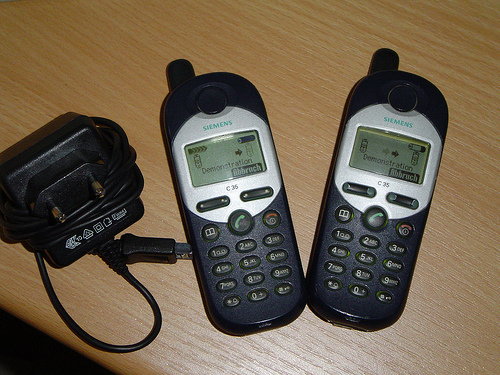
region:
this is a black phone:
[165, 37, 291, 320]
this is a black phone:
[311, 80, 454, 322]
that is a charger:
[7, 135, 165, 251]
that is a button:
[206, 245, 227, 256]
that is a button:
[236, 233, 251, 250]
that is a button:
[267, 251, 287, 261]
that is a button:
[247, 286, 262, 302]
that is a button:
[323, 256, 336, 271]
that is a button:
[350, 228, 381, 249]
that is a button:
[322, 277, 347, 292]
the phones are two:
[169, 68, 430, 326]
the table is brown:
[272, 338, 402, 373]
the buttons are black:
[221, 230, 286, 296]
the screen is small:
[177, 128, 274, 187]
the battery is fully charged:
[236, 128, 258, 148]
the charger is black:
[18, 126, 172, 331]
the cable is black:
[57, 308, 172, 371]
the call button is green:
[230, 213, 255, 230]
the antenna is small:
[165, 58, 200, 83]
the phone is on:
[338, 45, 440, 331]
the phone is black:
[338, 75, 438, 326]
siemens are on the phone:
[381, 110, 427, 133]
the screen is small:
[355, 129, 432, 185]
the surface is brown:
[270, 31, 332, 116]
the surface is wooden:
[280, 13, 330, 109]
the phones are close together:
[161, 69, 438, 323]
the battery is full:
[237, 134, 258, 147]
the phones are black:
[157, 54, 432, 331]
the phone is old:
[154, 60, 305, 326]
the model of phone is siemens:
[162, 74, 311, 340]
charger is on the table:
[19, 110, 200, 341]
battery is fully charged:
[234, 131, 261, 145]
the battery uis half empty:
[405, 145, 428, 154]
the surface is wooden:
[272, 54, 318, 141]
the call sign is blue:
[365, 210, 385, 225]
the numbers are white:
[226, 237, 293, 301]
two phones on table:
[150, 65, 412, 340]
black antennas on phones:
[362, 41, 396, 76]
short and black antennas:
[350, 41, 397, 86]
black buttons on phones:
[330, 202, 402, 315]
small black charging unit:
[39, 93, 176, 364]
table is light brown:
[5, 9, 127, 105]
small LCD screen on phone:
[160, 120, 294, 207]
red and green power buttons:
[224, 207, 277, 234]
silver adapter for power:
[171, 235, 188, 275]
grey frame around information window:
[191, 127, 271, 209]